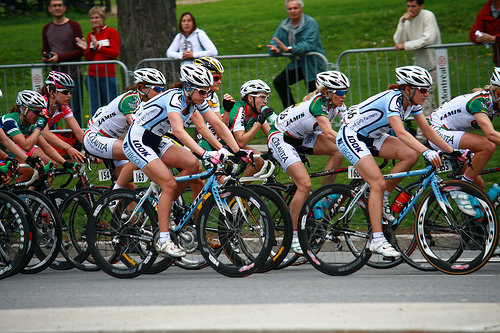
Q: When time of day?
A: Daytime.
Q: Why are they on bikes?
A: In a race.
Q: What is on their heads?
A: Helmets.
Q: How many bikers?
A: 9.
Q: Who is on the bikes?
A: Women.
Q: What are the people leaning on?
A: Gate.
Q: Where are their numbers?
A: On their backs.